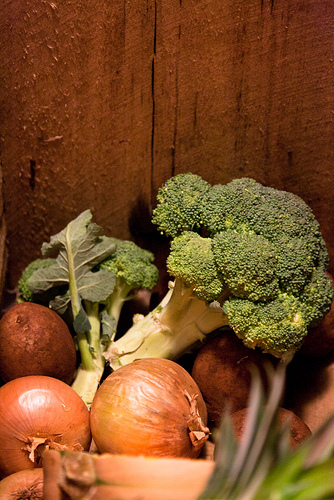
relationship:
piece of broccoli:
[146, 198, 312, 355] [139, 174, 333, 355]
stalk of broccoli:
[110, 282, 239, 351] [139, 174, 333, 355]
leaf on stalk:
[25, 207, 117, 334] [110, 282, 239, 351]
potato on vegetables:
[12, 300, 68, 363] [15, 170, 313, 497]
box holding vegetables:
[5, 3, 333, 188] [15, 170, 313, 497]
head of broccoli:
[152, 175, 328, 302] [139, 174, 333, 355]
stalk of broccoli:
[110, 282, 239, 373] [139, 174, 333, 355]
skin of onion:
[113, 389, 176, 427] [82, 355, 245, 498]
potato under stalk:
[12, 300, 68, 363] [110, 282, 239, 351]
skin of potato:
[16, 301, 41, 351] [12, 300, 68, 363]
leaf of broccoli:
[25, 207, 117, 334] [139, 174, 333, 355]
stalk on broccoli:
[110, 282, 239, 351] [139, 174, 333, 355]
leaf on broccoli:
[52, 207, 122, 328] [139, 174, 333, 355]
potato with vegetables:
[12, 300, 68, 363] [15, 170, 313, 497]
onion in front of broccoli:
[82, 355, 245, 498] [139, 174, 333, 355]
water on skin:
[129, 366, 155, 381] [113, 389, 176, 427]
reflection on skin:
[122, 382, 154, 414] [113, 389, 176, 427]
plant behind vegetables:
[22, 30, 301, 201] [15, 170, 313, 497]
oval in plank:
[20, 148, 49, 189] [5, 6, 331, 246]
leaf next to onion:
[25, 207, 117, 334] [82, 355, 245, 498]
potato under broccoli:
[12, 300, 68, 363] [139, 174, 333, 355]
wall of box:
[6, 5, 333, 203] [0, 0, 334, 316]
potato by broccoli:
[12, 300, 68, 363] [139, 174, 333, 355]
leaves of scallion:
[212, 428, 326, 492] [225, 427, 322, 499]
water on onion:
[129, 366, 155, 381] [82, 355, 245, 498]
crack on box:
[143, 14, 164, 188] [0, 0, 334, 316]